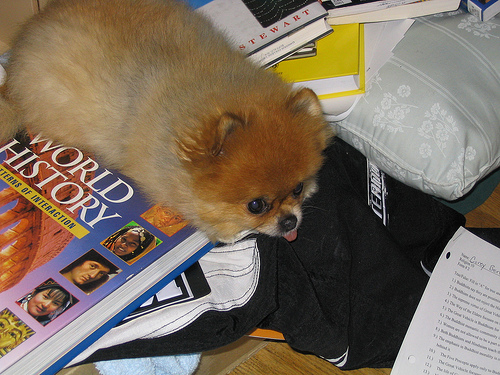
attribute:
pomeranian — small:
[15, 19, 344, 276]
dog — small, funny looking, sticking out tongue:
[186, 94, 313, 207]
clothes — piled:
[232, 260, 399, 347]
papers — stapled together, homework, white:
[449, 246, 490, 364]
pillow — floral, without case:
[373, 26, 488, 205]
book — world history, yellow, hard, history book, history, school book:
[7, 145, 191, 338]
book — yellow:
[272, 40, 359, 109]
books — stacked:
[219, 19, 312, 81]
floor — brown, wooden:
[262, 349, 299, 368]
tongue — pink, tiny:
[280, 229, 303, 245]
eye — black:
[238, 193, 289, 240]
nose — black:
[270, 212, 313, 246]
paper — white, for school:
[438, 240, 461, 274]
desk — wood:
[466, 209, 497, 226]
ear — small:
[288, 97, 330, 131]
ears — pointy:
[197, 96, 351, 135]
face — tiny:
[232, 133, 328, 253]